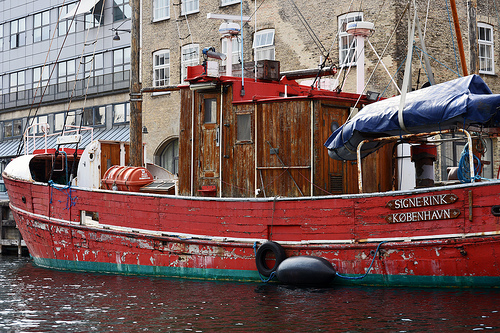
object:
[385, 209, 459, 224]
lettering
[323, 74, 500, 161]
blue tarp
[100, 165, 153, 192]
barrel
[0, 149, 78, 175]
front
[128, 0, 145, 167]
wooden pole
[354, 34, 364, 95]
pole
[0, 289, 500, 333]
river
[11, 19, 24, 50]
window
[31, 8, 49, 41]
window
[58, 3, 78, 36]
window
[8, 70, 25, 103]
window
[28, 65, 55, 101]
window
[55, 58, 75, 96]
window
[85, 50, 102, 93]
window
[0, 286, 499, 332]
water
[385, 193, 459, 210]
name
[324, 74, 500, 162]
covering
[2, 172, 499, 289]
boat paint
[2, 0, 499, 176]
building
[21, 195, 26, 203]
hole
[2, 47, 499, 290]
boat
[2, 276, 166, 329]
still water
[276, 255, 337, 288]
black object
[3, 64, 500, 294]
red boat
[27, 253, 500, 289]
green wood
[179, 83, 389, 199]
dark brown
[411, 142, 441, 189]
one person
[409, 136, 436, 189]
person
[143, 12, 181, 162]
brick building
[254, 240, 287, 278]
black tire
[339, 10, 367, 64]
window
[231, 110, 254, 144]
small window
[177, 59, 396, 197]
cabin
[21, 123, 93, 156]
white railing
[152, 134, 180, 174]
curved doorway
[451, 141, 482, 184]
blue hose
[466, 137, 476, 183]
pole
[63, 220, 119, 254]
wooden fence